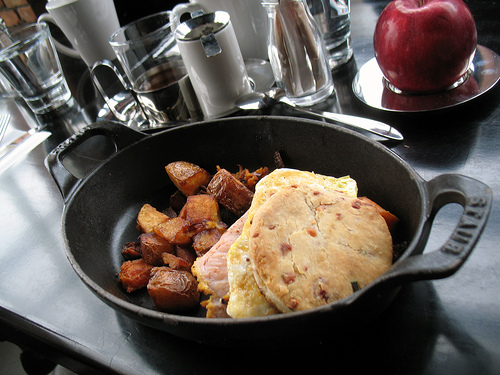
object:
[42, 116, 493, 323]
pan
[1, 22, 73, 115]
glass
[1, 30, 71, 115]
water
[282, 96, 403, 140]
knife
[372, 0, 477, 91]
apple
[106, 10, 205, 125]
water glass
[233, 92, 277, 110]
spoon